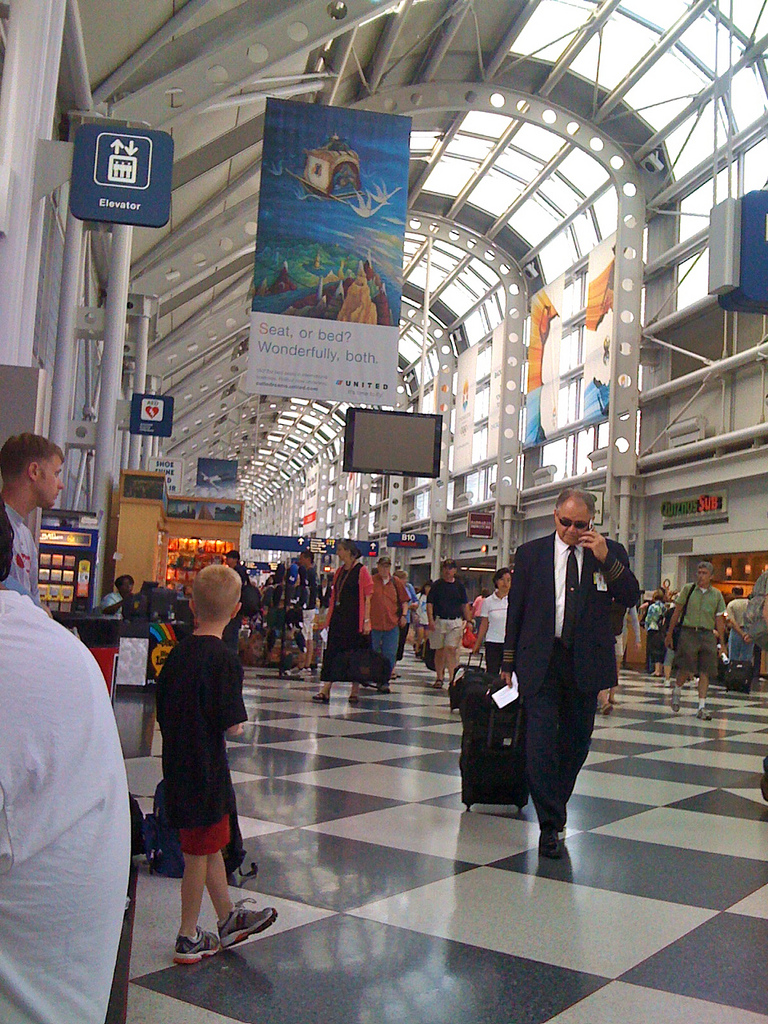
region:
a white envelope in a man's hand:
[488, 671, 523, 711]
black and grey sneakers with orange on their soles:
[169, 900, 288, 969]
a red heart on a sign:
[119, 392, 180, 438]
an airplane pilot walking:
[490, 490, 643, 878]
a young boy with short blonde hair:
[147, 564, 284, 972]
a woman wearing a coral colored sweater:
[307, 532, 376, 708]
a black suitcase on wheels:
[447, 673, 535, 820]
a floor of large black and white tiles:
[123, 625, 765, 1023]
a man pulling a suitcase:
[466, 494, 631, 858]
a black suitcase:
[455, 668, 523, 802]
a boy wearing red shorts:
[166, 565, 275, 963]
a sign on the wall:
[659, 496, 736, 522]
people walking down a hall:
[212, 540, 756, 813]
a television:
[349, 410, 442, 481]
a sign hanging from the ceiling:
[258, 98, 400, 408]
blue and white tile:
[294, 858, 747, 997]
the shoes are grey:
[160, 889, 303, 983]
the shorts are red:
[180, 810, 230, 854]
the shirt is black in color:
[151, 642, 282, 809]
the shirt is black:
[526, 816, 574, 862]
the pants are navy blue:
[509, 669, 604, 818]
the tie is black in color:
[562, 552, 588, 643]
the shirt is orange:
[365, 575, 405, 632]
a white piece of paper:
[489, 675, 518, 710]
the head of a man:
[550, 486, 607, 545]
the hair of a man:
[557, 488, 592, 505]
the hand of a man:
[559, 521, 613, 569]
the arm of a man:
[592, 545, 657, 619]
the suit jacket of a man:
[506, 528, 637, 690]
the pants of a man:
[506, 655, 600, 841]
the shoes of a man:
[528, 809, 582, 868]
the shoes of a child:
[125, 916, 322, 973]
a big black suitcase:
[445, 681, 548, 823]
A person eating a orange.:
[335, 355, 479, 492]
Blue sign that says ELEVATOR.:
[71, 122, 175, 227]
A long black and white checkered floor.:
[122, 649, 764, 1023]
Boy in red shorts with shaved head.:
[153, 563, 279, 965]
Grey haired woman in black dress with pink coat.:
[313, 538, 375, 704]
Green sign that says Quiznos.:
[658, 497, 698, 517]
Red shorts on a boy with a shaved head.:
[176, 813, 231, 855]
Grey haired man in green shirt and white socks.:
[662, 562, 730, 722]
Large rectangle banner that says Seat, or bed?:
[238, 95, 413, 407]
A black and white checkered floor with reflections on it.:
[123, 644, 765, 1021]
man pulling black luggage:
[454, 477, 641, 862]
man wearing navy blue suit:
[498, 482, 641, 860]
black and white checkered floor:
[125, 640, 766, 1019]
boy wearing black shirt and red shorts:
[149, 561, 282, 966]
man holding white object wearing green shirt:
[656, 553, 732, 731]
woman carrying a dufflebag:
[309, 529, 396, 706]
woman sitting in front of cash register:
[95, 568, 160, 618]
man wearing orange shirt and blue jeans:
[369, 547, 411, 697]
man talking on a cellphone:
[497, 485, 639, 861]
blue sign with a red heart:
[125, 385, 175, 442]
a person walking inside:
[541, 510, 655, 836]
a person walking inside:
[348, 543, 457, 740]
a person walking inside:
[315, 541, 413, 727]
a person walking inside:
[399, 543, 484, 672]